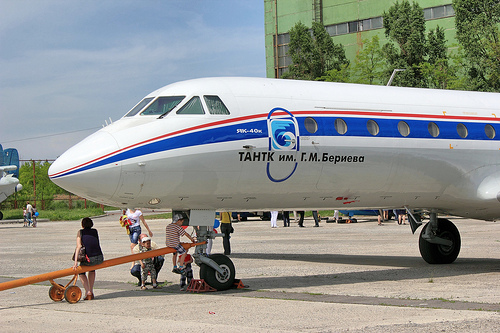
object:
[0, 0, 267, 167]
sky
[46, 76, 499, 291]
plane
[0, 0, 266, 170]
clouds